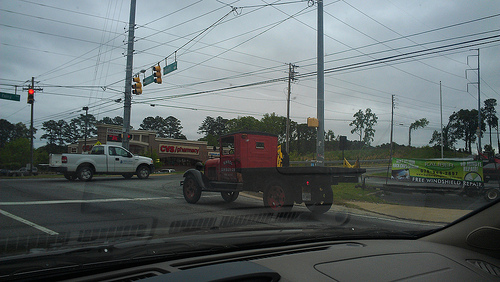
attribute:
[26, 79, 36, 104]
light — red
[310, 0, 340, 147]
poles — metal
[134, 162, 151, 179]
wheel — on a pickup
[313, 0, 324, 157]
pole — straight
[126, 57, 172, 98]
lights — yellow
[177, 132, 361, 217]
truck — antique, flat bed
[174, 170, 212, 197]
wheel — flatbed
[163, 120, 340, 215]
truck — antique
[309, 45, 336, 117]
pole — long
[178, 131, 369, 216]
antique truck — flatbed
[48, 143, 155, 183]
truck — white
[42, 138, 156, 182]
truck — pickup, white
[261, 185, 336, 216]
wheels — flatbed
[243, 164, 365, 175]
bed — empty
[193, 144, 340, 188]
truck — antique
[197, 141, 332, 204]
truck — antique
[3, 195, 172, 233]
lines — white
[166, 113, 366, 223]
truck — red